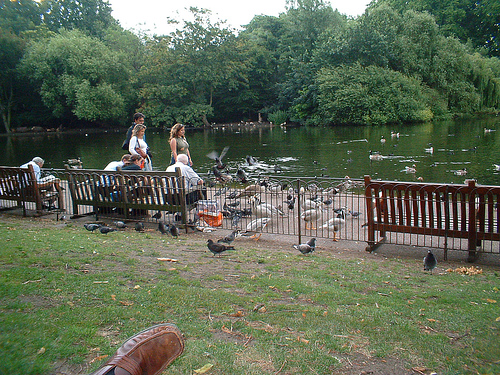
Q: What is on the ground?
A: Pigeons.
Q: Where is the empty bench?
A: On the right.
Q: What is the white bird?
A: It is a duck.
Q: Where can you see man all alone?
A: Bench on the left.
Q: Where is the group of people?
A: Near bench in the middle.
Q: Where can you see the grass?
A: Under the shoe.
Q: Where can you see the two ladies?
A: Standing in front of bench.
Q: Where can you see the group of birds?
A: On the sidewalk.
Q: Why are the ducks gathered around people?
A: Food.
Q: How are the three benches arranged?
A: In a row.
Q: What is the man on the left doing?
A: Reading.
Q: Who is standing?
A: Three people.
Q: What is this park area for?
A: Recreation.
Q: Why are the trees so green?
A: Plenty of water.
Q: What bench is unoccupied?
A: On the right.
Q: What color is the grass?
A: Green.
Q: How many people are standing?
A: Three.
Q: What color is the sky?
A: Gray.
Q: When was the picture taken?
A: Daytime.